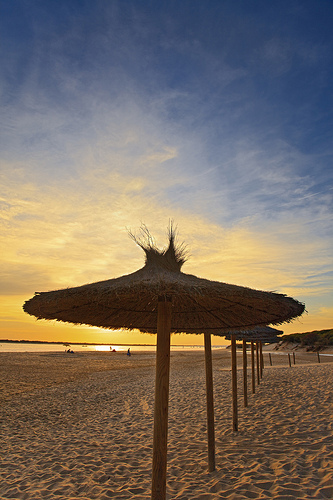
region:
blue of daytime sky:
[0, 1, 330, 152]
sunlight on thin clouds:
[3, 214, 275, 339]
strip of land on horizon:
[1, 338, 156, 346]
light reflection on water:
[0, 344, 219, 350]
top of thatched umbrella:
[23, 258, 306, 330]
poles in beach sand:
[154, 333, 265, 499]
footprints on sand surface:
[4, 351, 330, 498]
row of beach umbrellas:
[23, 255, 305, 497]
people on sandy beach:
[65, 345, 132, 354]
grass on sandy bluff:
[276, 328, 332, 353]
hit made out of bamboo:
[44, 258, 303, 333]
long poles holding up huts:
[154, 335, 267, 499]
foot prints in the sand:
[1, 430, 331, 498]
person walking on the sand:
[124, 344, 130, 361]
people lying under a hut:
[55, 341, 87, 365]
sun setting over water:
[92, 326, 120, 334]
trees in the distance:
[282, 329, 327, 347]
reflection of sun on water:
[92, 345, 121, 353]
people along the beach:
[175, 340, 202, 356]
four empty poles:
[264, 354, 328, 368]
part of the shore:
[287, 422, 294, 430]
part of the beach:
[279, 421, 290, 444]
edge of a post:
[146, 418, 156, 435]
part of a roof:
[194, 297, 203, 310]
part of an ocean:
[112, 346, 117, 350]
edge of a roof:
[180, 279, 188, 289]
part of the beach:
[286, 377, 302, 413]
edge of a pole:
[191, 447, 243, 490]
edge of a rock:
[305, 327, 312, 344]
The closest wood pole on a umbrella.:
[151, 294, 171, 499]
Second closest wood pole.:
[203, 331, 214, 472]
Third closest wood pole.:
[229, 333, 239, 431]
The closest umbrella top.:
[20, 217, 305, 333]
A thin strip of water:
[0, 340, 225, 353]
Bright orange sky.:
[2, 294, 233, 343]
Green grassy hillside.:
[282, 327, 331, 355]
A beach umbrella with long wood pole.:
[22, 217, 305, 498]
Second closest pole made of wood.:
[203, 331, 214, 473]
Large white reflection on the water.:
[91, 343, 126, 352]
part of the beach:
[267, 411, 279, 427]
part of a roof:
[224, 299, 232, 315]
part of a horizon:
[62, 342, 66, 352]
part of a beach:
[87, 360, 96, 373]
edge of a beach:
[94, 405, 116, 438]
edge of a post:
[150, 446, 165, 468]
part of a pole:
[205, 448, 223, 466]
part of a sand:
[280, 411, 290, 433]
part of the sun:
[103, 358, 106, 381]